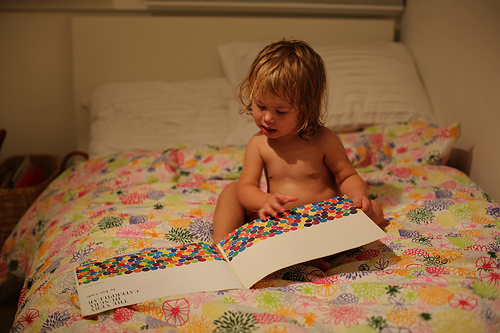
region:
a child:
[206, 33, 392, 273]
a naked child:
[203, 34, 390, 274]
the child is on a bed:
[16, 28, 493, 330]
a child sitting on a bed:
[62, 20, 484, 327]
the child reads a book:
[70, 33, 390, 318]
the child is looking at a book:
[63, 28, 405, 328]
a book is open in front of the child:
[67, 33, 397, 318]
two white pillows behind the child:
[75, 25, 445, 160]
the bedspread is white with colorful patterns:
[30, 114, 495, 331]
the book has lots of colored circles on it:
[51, 195, 392, 330]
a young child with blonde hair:
[216, 29, 351, 158]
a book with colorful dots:
[56, 193, 389, 315]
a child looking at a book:
[70, 35, 392, 309]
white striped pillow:
[84, 66, 264, 169]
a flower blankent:
[42, 155, 193, 248]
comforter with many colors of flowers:
[52, 148, 210, 253]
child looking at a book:
[198, 25, 368, 282]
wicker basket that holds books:
[0, 152, 70, 252]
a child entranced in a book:
[183, 17, 383, 288]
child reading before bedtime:
[93, 32, 441, 285]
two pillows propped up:
[82, 38, 431, 155]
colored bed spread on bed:
[12, 124, 496, 331]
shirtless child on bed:
[211, 37, 383, 242]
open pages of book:
[76, 192, 388, 319]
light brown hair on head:
[242, 41, 325, 135]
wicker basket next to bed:
[0, 150, 64, 231]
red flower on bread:
[160, 296, 190, 329]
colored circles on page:
[220, 195, 357, 259]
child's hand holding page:
[351, 195, 374, 216]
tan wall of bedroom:
[404, 2, 498, 188]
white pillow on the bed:
[215, 38, 437, 135]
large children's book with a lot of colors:
[74, 190, 386, 317]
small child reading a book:
[211, 38, 386, 243]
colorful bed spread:
[5, 119, 494, 328]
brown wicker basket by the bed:
[1, 150, 61, 231]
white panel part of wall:
[68, 12, 408, 149]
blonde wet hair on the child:
[237, 36, 327, 140]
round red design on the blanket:
[163, 295, 192, 325]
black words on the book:
[83, 285, 140, 311]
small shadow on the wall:
[450, 143, 472, 172]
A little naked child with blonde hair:
[210, 34, 395, 271]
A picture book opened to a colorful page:
[52, 192, 390, 320]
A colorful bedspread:
[0, 119, 498, 326]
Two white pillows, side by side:
[73, 37, 437, 163]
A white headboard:
[65, 13, 399, 161]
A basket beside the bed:
[2, 137, 66, 237]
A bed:
[5, 9, 495, 331]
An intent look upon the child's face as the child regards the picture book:
[248, 89, 298, 140]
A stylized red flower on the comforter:
[154, 296, 194, 331]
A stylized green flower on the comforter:
[204, 307, 256, 332]